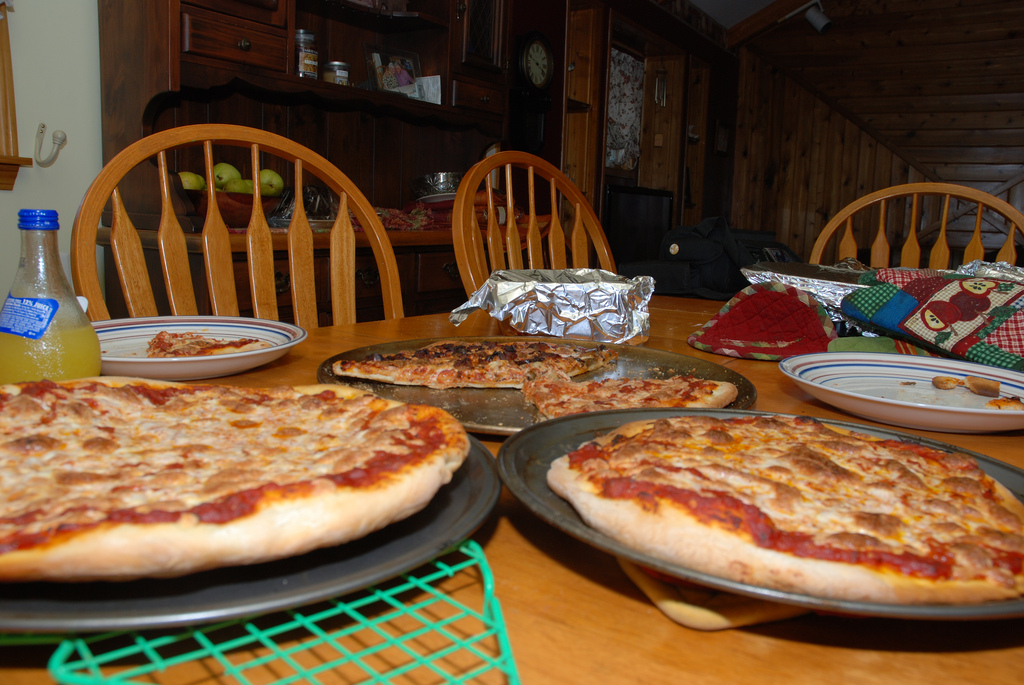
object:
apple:
[213, 162, 241, 188]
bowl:
[184, 187, 285, 226]